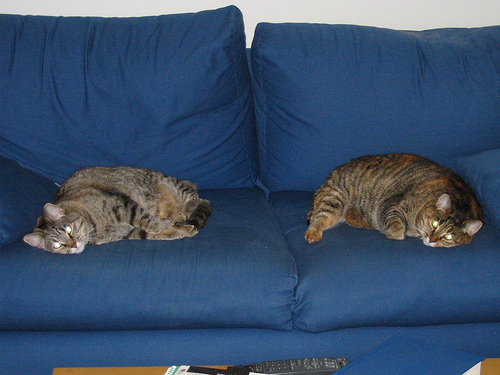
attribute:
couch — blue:
[137, 28, 275, 168]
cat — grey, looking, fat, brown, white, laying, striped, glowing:
[64, 184, 181, 241]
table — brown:
[101, 365, 134, 373]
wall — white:
[327, 2, 397, 17]